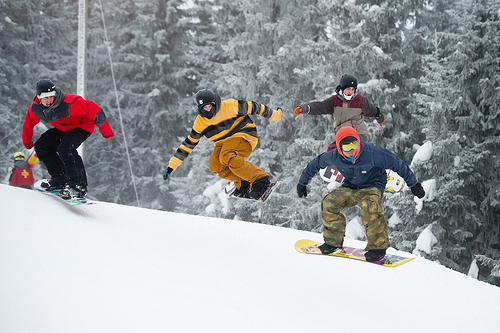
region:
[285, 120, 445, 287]
the boy is snowboarding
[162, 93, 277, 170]
a black and yellow jacket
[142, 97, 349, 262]
these are some men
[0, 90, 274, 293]
these are some snowboarders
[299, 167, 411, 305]
the board is yellow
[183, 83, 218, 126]
this is a hat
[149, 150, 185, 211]
this is a glove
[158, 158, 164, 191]
the glove is black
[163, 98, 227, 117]
the hat is black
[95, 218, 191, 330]
this is a mountain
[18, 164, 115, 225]
the board is blue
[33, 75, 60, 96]
Person wearing black hat.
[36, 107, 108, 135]
Person wearing red and gray coat.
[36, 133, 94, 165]
Person wearing black pants.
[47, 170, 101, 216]
Person on snow board.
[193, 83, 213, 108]
Person wearing dark hat.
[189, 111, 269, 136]
Person wearing black, gray, and yellow shirt.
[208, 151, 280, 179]
Person wearing golden brown pants.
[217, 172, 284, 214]
Person standing on snowboard.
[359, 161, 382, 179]
Person wearing blue jacket.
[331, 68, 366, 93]
Person wearing dark hat.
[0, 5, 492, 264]
pine trees behind slope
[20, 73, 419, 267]
four snowboarders on slope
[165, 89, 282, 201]
snowboarder jumping in the air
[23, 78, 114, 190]
man crouched forward over slope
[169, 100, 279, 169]
stripes on yellow shirt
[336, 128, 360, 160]
hat and goggles on man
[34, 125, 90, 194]
black pants on man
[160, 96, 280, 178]
extended arms of snowboarder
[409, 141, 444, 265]
snow on tree branches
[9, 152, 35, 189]
back of person behind slope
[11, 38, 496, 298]
The people are up in the mountains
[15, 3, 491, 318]
The people are at a ski resort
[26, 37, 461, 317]
The people are doing some snowboarding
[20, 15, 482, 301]
The people are having a great time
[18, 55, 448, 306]
The people are on their day off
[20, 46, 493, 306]
The people are wearing warm clothing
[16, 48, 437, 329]
The people are wearing hats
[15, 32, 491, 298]
The people are playing in the snow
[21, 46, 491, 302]
The people are out in the daytime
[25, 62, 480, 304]
The people are enjoying the day